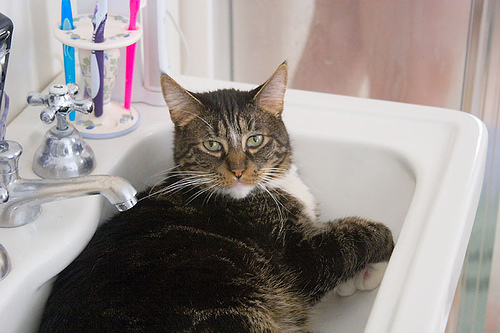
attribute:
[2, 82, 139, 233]
faucet — portion, long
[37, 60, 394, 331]
cat — pictured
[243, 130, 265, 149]
eye — green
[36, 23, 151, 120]
holder — white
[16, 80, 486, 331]
sink — ceramic, white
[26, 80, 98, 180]
handle — silver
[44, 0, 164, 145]
toothbrushes — one, tooth, pink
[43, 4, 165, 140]
toothbrush — pink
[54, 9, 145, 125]
holder — toothbrush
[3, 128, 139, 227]
faucet — edge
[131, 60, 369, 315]
cat — looking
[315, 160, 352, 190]
ground — siver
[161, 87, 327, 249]
cat — brown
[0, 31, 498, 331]
sink — dark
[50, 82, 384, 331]
cat — large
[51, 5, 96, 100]
toothbrush — blue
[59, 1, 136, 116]
toothbrush — turquoise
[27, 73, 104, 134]
handle — silver, water, faucet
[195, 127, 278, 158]
eyes — green